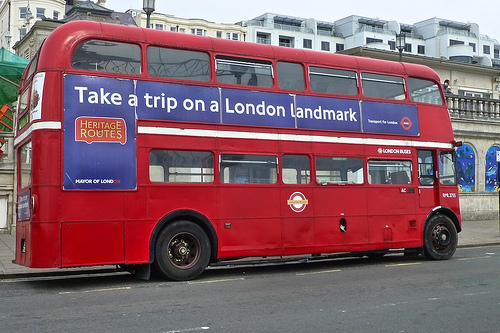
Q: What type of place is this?
A: It is a street.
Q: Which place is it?
A: It is a street.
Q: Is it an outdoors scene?
A: Yes, it is outdoors.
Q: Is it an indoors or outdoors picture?
A: It is outdoors.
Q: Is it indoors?
A: No, it is outdoors.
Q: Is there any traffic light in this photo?
A: No, there are no traffic lights.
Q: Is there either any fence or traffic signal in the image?
A: No, there are no traffic lights or fences.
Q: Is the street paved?
A: Yes, the street is paved.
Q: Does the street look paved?
A: Yes, the street is paved.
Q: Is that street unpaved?
A: No, the street is paved.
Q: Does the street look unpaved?
A: No, the street is paved.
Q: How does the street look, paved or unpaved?
A: The street is paved.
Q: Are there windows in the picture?
A: Yes, there is a window.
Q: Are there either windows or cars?
A: Yes, there is a window.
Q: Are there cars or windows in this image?
A: Yes, there is a window.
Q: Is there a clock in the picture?
A: No, there are no clocks.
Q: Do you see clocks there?
A: No, there are no clocks.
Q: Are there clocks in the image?
A: No, there are no clocks.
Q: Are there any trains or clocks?
A: No, there are no clocks or trains.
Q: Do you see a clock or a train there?
A: No, there are no clocks or trains.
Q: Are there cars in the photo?
A: No, there are no cars.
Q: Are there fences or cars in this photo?
A: No, there are no cars or fences.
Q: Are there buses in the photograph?
A: Yes, there is a bus.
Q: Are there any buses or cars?
A: Yes, there is a bus.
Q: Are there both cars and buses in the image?
A: No, there is a bus but no cars.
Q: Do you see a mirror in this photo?
A: No, there are no mirrors.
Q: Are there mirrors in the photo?
A: No, there are no mirrors.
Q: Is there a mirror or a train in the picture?
A: No, there are no mirrors or trains.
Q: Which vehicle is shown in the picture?
A: The vehicle is a bus.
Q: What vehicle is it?
A: The vehicle is a bus.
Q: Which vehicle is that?
A: This is a bus.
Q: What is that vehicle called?
A: This is a bus.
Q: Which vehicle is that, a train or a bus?
A: This is a bus.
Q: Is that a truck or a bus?
A: That is a bus.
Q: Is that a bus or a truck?
A: That is a bus.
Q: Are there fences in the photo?
A: No, there are no fences.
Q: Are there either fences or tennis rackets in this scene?
A: No, there are no fences or tennis rackets.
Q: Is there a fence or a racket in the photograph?
A: No, there are no fences or rackets.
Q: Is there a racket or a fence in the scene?
A: No, there are no fences or rackets.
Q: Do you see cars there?
A: No, there are no cars.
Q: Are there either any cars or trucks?
A: No, there are no cars or trucks.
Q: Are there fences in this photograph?
A: No, there are no fences.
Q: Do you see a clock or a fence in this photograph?
A: No, there are no fences or clocks.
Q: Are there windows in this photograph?
A: Yes, there is a window.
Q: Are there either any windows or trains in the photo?
A: Yes, there is a window.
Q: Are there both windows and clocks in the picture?
A: No, there is a window but no clocks.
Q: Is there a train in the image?
A: No, there are no trains.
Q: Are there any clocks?
A: No, there are no clocks.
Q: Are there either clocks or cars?
A: No, there are no clocks or cars.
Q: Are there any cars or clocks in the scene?
A: No, there are no clocks or cars.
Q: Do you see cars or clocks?
A: No, there are no clocks or cars.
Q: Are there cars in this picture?
A: No, there are no cars.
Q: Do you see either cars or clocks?
A: No, there are no cars or clocks.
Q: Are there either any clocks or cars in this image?
A: No, there are no cars or clocks.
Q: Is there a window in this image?
A: Yes, there is a window.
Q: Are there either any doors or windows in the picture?
A: Yes, there is a window.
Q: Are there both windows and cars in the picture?
A: No, there is a window but no cars.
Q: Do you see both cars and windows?
A: No, there is a window but no cars.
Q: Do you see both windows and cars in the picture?
A: No, there is a window but no cars.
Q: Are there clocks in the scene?
A: No, there are no clocks.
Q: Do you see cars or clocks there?
A: No, there are no clocks or cars.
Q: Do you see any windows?
A: Yes, there is a window.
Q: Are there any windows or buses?
A: Yes, there is a window.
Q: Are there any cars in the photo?
A: No, there are no cars.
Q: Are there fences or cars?
A: No, there are no cars or fences.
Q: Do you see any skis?
A: No, there are no skis.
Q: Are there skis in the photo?
A: No, there are no skis.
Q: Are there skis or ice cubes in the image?
A: No, there are no skis or ice cubes.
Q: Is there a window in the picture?
A: Yes, there is a window.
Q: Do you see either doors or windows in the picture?
A: Yes, there is a window.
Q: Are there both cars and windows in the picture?
A: No, there is a window but no cars.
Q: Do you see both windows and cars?
A: No, there is a window but no cars.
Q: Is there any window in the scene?
A: Yes, there is a window.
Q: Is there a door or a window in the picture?
A: Yes, there is a window.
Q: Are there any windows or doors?
A: Yes, there is a window.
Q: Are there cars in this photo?
A: No, there are no cars.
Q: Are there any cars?
A: No, there are no cars.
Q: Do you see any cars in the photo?
A: No, there are no cars.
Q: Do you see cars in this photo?
A: No, there are no cars.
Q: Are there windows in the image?
A: Yes, there are windows.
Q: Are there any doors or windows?
A: Yes, there are windows.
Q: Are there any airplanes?
A: No, there are no airplanes.